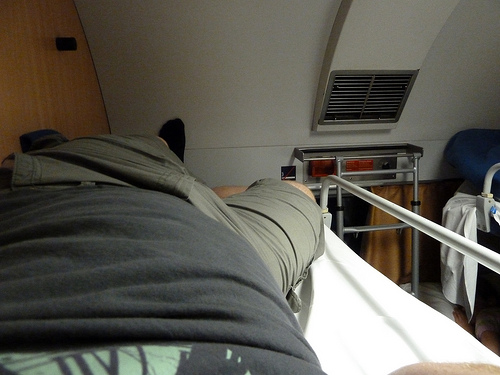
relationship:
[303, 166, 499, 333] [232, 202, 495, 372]
rail beside sheet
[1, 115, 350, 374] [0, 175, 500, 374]
man of bed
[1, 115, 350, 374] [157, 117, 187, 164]
man wearing sock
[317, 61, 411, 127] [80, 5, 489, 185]
air vent of wall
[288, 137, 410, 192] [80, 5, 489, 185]
machier of wall